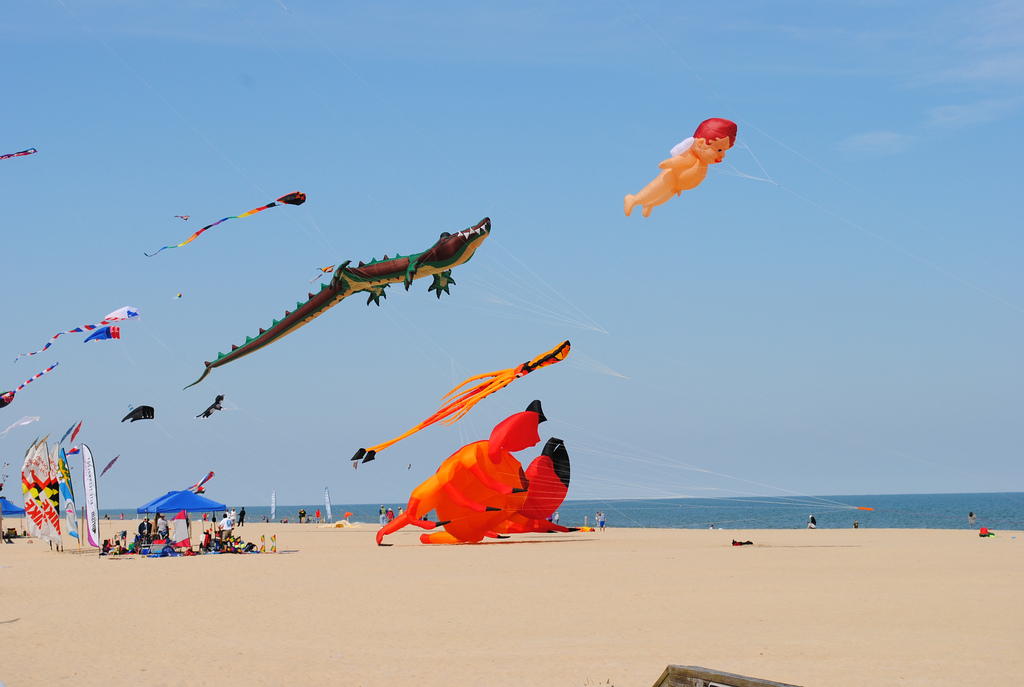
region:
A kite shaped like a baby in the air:
[628, 112, 743, 218]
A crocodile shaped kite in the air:
[186, 216, 493, 384]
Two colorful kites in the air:
[6, 300, 144, 409]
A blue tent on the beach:
[139, 481, 229, 519]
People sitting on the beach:
[96, 510, 258, 553]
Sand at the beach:
[2, 509, 1021, 684]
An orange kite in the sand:
[363, 398, 545, 548]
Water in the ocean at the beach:
[22, 490, 1016, 529]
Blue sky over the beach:
[5, 1, 901, 504]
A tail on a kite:
[3, 341, 83, 411]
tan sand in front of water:
[6, 515, 1021, 684]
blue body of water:
[68, 491, 1018, 527]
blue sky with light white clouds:
[3, 1, 1022, 492]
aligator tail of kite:
[173, 278, 339, 403]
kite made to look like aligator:
[177, 206, 529, 403]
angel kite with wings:
[610, 110, 743, 224]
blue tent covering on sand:
[125, 483, 234, 526]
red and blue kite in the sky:
[0, 316, 134, 416]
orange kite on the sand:
[369, 388, 553, 565]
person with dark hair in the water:
[957, 505, 984, 526]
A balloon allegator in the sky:
[157, 217, 537, 363]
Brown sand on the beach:
[462, 540, 757, 636]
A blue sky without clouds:
[593, 256, 1008, 428]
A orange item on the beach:
[375, 418, 604, 542]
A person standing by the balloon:
[592, 500, 612, 533]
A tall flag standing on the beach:
[80, 452, 103, 566]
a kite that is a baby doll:
[619, 101, 757, 232]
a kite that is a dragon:
[230, 198, 529, 304]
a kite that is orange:
[401, 341, 610, 399]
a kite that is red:
[432, 411, 589, 554]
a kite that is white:
[79, 281, 166, 335]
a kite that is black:
[108, 394, 173, 440]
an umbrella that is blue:
[148, 478, 209, 526]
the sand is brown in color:
[320, 563, 495, 653]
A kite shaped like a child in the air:
[621, 114, 742, 223]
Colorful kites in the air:
[3, 288, 137, 409]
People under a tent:
[84, 509, 261, 558]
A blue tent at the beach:
[129, 481, 231, 514]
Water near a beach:
[24, 493, 1020, 525]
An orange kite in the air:
[344, 339, 575, 467]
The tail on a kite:
[0, 339, 92, 404]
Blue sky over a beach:
[5, 3, 1015, 506]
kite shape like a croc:
[171, 170, 522, 402]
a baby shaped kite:
[613, 94, 762, 228]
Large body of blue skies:
[856, 101, 1006, 235]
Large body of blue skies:
[767, 306, 974, 421]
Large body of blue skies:
[285, 37, 459, 149]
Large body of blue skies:
[808, 73, 958, 200]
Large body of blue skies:
[113, 72, 272, 167]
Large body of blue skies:
[648, 325, 848, 418]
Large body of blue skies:
[808, 215, 990, 384]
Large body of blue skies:
[84, 13, 231, 138]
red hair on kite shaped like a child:
[619, 116, 737, 218]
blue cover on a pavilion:
[136, 489, 231, 516]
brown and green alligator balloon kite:
[189, 214, 490, 386]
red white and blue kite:
[19, 299, 138, 364]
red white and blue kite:
[0, 355, 65, 407]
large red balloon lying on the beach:
[379, 401, 583, 539]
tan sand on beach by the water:
[7, 514, 1019, 685]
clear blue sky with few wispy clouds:
[0, 2, 1016, 494]